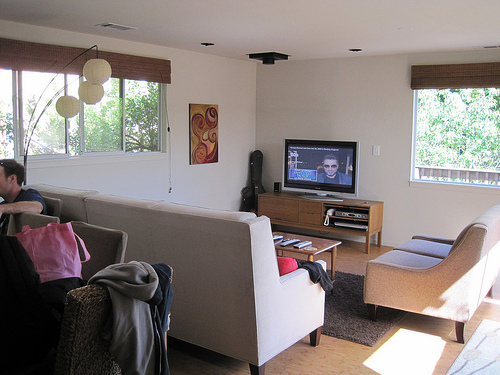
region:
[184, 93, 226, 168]
Paint hung on wall.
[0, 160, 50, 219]
Man sitting in chair.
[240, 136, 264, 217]
Black guitar case in corner.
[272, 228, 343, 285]
Brown wooden coffee table.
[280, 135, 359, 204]
Television on top of console.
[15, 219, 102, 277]
Light pink bag on chair.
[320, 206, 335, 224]
White telephone on shelf.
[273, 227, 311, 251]
Remotes on coffee table.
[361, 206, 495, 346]
Light beige loveseat with wooden feet..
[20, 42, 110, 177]
Curved lamp with three white globes.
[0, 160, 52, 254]
A man sitting down at the kitchen table.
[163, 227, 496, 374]
Brown hardwood floors.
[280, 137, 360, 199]
A silver and black framed television.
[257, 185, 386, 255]
A long wooden television stand.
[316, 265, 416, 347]
A brown rug.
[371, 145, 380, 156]
A white panel on the wall.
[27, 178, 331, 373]
A sofa.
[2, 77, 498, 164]
Green trees outside of the window.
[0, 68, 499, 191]
Windows.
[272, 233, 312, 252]
Remote controllers.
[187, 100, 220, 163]
A picture hanging on the wall.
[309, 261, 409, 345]
A dark brown area rug.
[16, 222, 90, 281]
A pink bag with pink handles.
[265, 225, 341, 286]
A wooden coffee stand.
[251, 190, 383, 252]
A wooden entertainment stand.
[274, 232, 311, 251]
Remote controllers on the coffee table.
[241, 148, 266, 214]
A black guitar case.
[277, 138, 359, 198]
A flatscreen television.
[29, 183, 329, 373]
A beige sofa.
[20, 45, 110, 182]
A lantern style floor lamp.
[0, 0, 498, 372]
A living room scene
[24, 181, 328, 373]
A white couch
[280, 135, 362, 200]
A flat screen television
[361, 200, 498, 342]
This is a love seat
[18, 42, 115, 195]
A light is above the couch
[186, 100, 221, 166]
A painting is above the wall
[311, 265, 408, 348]
A rug is on the floor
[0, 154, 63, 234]
A man is sitting behind the couch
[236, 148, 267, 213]
A guitar case is in the corner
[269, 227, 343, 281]
A coffee table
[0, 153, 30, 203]
the head of a man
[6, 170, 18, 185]
the ear of a man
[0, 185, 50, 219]
the arm of a man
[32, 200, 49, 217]
the elbow of a man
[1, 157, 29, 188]
the hair of a man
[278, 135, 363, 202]
a television on the table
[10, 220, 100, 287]
a pink bag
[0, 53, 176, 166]
a row of windows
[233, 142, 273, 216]
a guitar case in the corner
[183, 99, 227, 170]
a painting on the wall